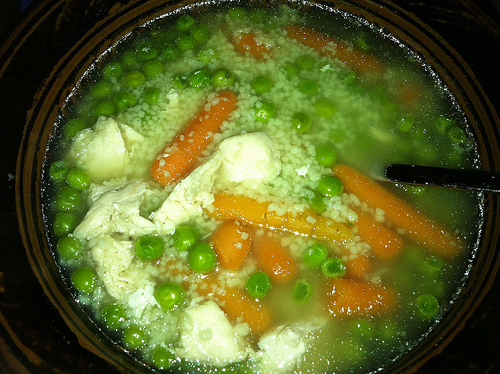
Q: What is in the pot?
A: Carrots.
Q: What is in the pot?
A: Pasta.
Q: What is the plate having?
A: Soup.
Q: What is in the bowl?
A: Soup.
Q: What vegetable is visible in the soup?
A: Peas.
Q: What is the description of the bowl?
A: A black and gold bowl.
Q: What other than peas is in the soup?
A: Whole carrots.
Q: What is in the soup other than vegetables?
A: Chunks of white meat.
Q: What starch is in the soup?
A: Pieces of noodle.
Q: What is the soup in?
A: A bowl.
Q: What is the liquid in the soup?
A: A broth.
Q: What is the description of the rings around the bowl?
A: Gold rings.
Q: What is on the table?
A: Bowl of soup.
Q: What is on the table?
A: Bowl of soup.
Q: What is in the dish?
A: Carrots.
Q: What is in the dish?
A: Carrots.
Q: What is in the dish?
A: Peas.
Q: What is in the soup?
A: Carrots.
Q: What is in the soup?
A: Carrots.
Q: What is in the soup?
A: Carrots.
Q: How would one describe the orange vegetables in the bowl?
A: Carrot cut to have smooth rounded ends.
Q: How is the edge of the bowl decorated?
A: Alternating dark and brown stripes.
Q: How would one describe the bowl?
A: Round and brown.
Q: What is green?
A: Peas.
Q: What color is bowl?
A: Brown.